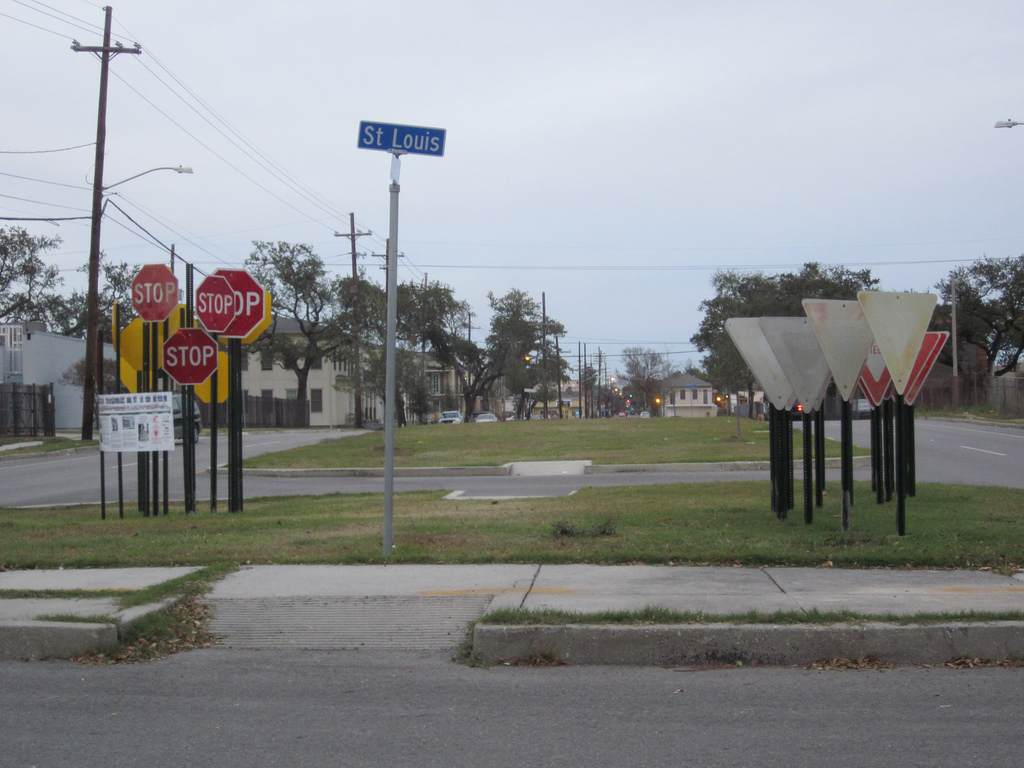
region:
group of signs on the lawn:
[700, 266, 961, 568]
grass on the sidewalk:
[498, 603, 658, 624]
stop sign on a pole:
[125, 260, 186, 324]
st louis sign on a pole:
[351, 113, 460, 167]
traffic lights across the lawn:
[604, 379, 665, 419]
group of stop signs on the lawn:
[117, 243, 277, 384]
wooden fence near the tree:
[248, 394, 312, 430]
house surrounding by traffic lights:
[661, 369, 713, 417]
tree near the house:
[339, 277, 379, 432]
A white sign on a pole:
[90, 386, 188, 457]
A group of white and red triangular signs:
[719, 285, 951, 539]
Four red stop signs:
[126, 261, 254, 497]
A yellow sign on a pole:
[117, 314, 152, 504]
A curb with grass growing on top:
[457, 604, 1021, 678]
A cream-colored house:
[654, 362, 722, 417]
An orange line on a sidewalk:
[404, 583, 601, 603]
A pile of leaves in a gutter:
[110, 624, 210, 662]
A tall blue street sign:
[344, 112, 446, 550]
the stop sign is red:
[194, 273, 233, 325]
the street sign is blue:
[356, 117, 442, 156]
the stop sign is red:
[157, 326, 211, 381]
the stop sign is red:
[217, 272, 265, 334]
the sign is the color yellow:
[117, 320, 144, 366]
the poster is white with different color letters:
[94, 389, 172, 451]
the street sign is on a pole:
[351, 119, 446, 562]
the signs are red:
[903, 329, 945, 403]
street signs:
[722, 277, 958, 446]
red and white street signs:
[96, 218, 280, 396]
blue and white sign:
[351, 104, 447, 171]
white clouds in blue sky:
[810, 116, 897, 206]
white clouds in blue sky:
[219, 51, 309, 144]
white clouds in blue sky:
[465, 206, 576, 276]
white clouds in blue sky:
[599, 43, 710, 145]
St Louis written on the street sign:
[353, 113, 447, 164]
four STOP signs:
[129, 257, 270, 385]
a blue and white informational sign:
[353, 116, 448, 158]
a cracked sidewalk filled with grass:
[1, 555, 1023, 616]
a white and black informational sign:
[89, 390, 178, 452]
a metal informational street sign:
[350, 110, 449, 560]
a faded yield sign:
[798, 292, 871, 537]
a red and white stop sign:
[121, 262, 182, 320]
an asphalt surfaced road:
[0, 463, 1016, 493]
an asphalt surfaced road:
[0, 658, 1018, 764]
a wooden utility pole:
[68, 3, 145, 440]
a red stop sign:
[127, 261, 179, 322]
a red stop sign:
[193, 273, 238, 331]